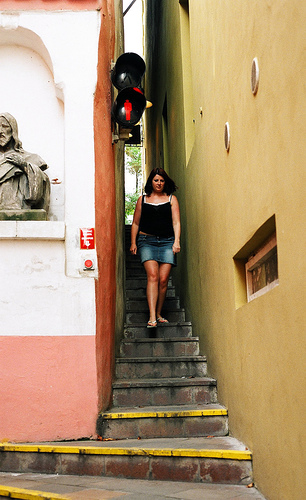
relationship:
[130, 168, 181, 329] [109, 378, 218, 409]
girl on stair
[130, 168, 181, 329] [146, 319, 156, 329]
girl on flip flops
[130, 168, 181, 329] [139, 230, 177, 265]
girl wearing skirt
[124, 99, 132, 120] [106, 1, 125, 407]
man logo attached to wall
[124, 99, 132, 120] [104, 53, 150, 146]
man logo of lamp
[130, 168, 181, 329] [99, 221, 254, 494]
girl descending staircase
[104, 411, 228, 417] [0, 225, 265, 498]
edge on staircase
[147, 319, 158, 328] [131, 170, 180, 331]
flip flops on girl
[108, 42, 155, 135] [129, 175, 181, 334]
black balloons above girl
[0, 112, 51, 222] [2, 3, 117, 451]
figure on wall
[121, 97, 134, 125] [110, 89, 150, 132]
man logo on balloon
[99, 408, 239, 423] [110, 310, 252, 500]
edge on staircase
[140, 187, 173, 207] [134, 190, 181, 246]
border on shirt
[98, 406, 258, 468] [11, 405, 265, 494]
edge of steps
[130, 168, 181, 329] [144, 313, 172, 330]
girl wearing flip flops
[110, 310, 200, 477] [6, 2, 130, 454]
staircase between building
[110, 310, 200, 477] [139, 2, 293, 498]
staircase between building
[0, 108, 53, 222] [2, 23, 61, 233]
figure inside window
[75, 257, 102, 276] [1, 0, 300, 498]
red button on building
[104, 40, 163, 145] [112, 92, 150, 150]
lamp behind light